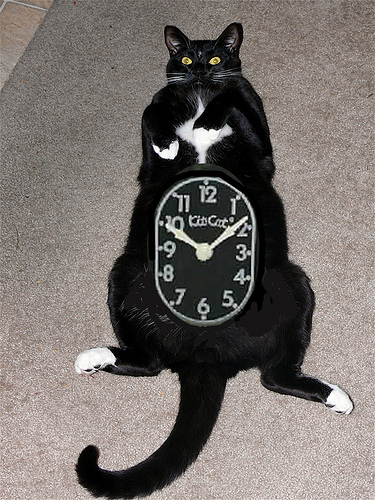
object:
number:
[198, 180, 218, 204]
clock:
[154, 175, 258, 328]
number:
[228, 195, 240, 217]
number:
[236, 243, 251, 261]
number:
[232, 268, 246, 286]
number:
[221, 289, 238, 309]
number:
[196, 298, 210, 321]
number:
[169, 288, 187, 306]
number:
[159, 264, 175, 283]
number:
[159, 240, 177, 259]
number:
[165, 214, 185, 233]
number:
[236, 220, 252, 238]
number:
[172, 192, 191, 214]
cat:
[77, 21, 354, 499]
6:
[197, 297, 211, 320]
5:
[221, 289, 238, 309]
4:
[232, 268, 250, 286]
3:
[235, 243, 247, 261]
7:
[169, 288, 186, 306]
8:
[159, 264, 175, 283]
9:
[158, 240, 177, 259]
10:
[165, 214, 184, 235]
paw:
[193, 116, 221, 146]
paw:
[151, 131, 179, 161]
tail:
[75, 381, 227, 499]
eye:
[208, 55, 222, 66]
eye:
[180, 56, 194, 66]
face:
[167, 42, 240, 104]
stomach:
[140, 160, 267, 336]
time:
[160, 214, 251, 262]